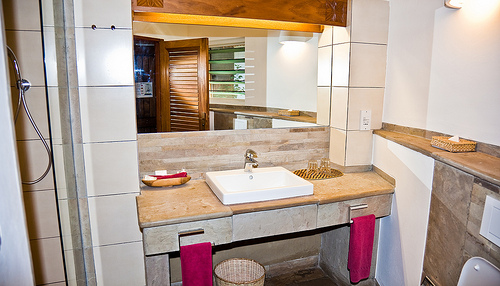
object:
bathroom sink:
[209, 165, 311, 194]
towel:
[178, 242, 216, 285]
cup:
[316, 157, 333, 175]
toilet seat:
[450, 255, 499, 285]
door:
[152, 35, 211, 133]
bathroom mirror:
[134, 18, 332, 135]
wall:
[423, 0, 500, 160]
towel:
[343, 213, 378, 285]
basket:
[212, 256, 268, 285]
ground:
[264, 264, 350, 285]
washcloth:
[147, 168, 187, 181]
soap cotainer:
[138, 168, 193, 191]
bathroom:
[0, 1, 499, 284]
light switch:
[356, 108, 373, 133]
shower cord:
[3, 46, 54, 186]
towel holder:
[345, 202, 370, 213]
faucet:
[242, 147, 261, 173]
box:
[427, 135, 476, 154]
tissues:
[446, 135, 460, 142]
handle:
[176, 226, 205, 239]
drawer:
[141, 215, 235, 257]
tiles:
[344, 86, 389, 132]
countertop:
[135, 162, 393, 229]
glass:
[307, 157, 324, 173]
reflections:
[135, 20, 321, 136]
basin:
[200, 165, 315, 207]